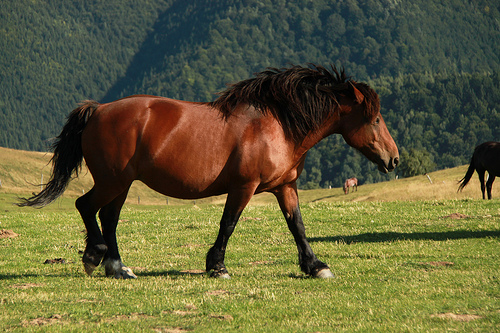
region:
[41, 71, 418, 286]
large horse on field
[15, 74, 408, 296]
large horse walking on a fiedl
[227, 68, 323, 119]
black mane of a horse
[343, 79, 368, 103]
brown ear of horse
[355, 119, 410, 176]
brown long face of horse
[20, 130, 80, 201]
bushy black tail of horse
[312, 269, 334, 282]
large grey hooves of horse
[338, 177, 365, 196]
brown and white horse grazing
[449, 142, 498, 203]
back end of black horse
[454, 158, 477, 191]
black tail of large horse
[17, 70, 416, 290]
large brown horse on field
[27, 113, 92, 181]
black tail of horse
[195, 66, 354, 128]
black mane of horse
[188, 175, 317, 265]
brown and black legs of horse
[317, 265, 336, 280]
grey hooves of horse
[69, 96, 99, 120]
brown on top of horse tail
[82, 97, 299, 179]
brown body of horse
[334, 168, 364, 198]
horse grazing in field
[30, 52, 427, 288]
Horse in the field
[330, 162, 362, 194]
Horse in the field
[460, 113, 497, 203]
Horse in the field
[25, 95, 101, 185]
horse with long hair on its tail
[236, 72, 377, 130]
horse with brown hair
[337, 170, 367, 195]
horse with its head down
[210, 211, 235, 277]
horse with black legs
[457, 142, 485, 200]
horse with black hair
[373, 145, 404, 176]
horse with a brown nose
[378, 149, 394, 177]
horse with its mouth closed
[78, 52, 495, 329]
a horse on a field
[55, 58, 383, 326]
a brown horse on a field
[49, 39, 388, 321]
a horse walking on a field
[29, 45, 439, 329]
a brown horse walking on a field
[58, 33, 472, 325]
a horse walking outside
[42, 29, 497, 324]
a brown horse walking outside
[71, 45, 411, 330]
a horse running in a field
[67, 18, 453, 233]
a horse running on the grass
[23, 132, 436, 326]
a field of grass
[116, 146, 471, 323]
a field of green grass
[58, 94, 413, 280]
A brown and black horse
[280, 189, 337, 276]
A brown and black horse's feet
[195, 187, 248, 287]
A brown and black horse's feet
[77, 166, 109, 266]
A brown and black horse's feet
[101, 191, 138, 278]
A brown and black horse's feet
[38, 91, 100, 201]
A brown and black horse's tail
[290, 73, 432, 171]
A brown and black horse's head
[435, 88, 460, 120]
A short green tree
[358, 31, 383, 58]
A short green tree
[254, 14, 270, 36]
A short green tree